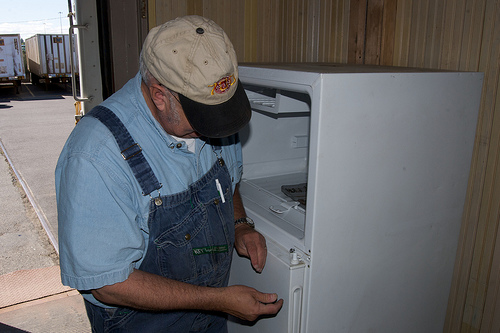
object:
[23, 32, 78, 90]
trailer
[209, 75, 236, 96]
logo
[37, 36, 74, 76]
back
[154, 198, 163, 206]
button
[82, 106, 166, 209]
strap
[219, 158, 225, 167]
button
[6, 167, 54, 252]
ground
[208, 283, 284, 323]
hand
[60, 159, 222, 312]
arm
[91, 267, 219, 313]
skin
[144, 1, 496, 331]
wall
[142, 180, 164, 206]
buckle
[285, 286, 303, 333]
handle section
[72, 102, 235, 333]
overalls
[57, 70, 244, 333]
clothes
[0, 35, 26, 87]
trucks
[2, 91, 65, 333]
yard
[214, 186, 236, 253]
pocket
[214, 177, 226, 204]
pen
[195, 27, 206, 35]
tip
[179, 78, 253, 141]
bill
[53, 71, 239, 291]
blue sleeve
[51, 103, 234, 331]
overall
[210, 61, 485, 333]
freezer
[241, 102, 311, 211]
inside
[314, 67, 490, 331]
fridge side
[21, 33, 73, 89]
trucks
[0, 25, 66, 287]
parking lot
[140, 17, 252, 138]
cap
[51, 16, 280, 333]
guy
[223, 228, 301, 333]
refrigerator door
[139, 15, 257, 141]
head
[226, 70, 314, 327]
door